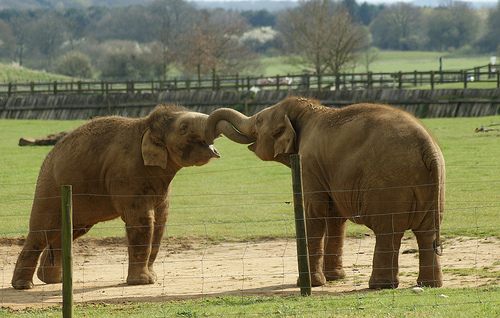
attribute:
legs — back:
[6, 196, 168, 290]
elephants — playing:
[13, 87, 452, 298]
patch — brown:
[1, 235, 498, 300]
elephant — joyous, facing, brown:
[198, 92, 451, 295]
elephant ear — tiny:
[270, 113, 299, 161]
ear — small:
[270, 113, 297, 159]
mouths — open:
[194, 120, 322, 209]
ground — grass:
[399, 132, 440, 159]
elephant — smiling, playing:
[11, 105, 253, 287]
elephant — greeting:
[222, 68, 428, 314]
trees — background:
[52, 1, 374, 82]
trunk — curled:
[201, 106, 254, 143]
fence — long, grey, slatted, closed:
[4, 72, 498, 122]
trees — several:
[11, 6, 499, 58]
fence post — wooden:
[272, 146, 322, 316]